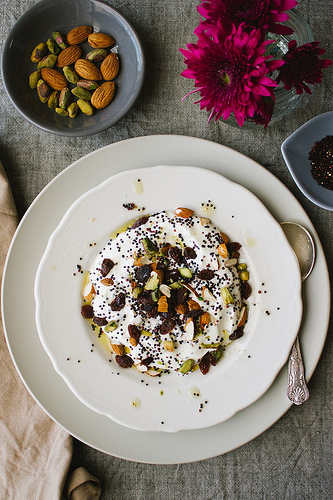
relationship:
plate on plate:
[3, 133, 332, 468] [3, 133, 332, 468]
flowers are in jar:
[185, 1, 326, 120] [208, 7, 314, 131]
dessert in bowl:
[81, 207, 252, 378] [38, 166, 302, 427]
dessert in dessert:
[81, 207, 252, 378] [81, 207, 252, 378]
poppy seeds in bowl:
[310, 134, 330, 188] [280, 111, 333, 211]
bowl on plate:
[35, 165, 304, 432] [3, 133, 332, 468]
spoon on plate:
[278, 219, 318, 405] [3, 133, 332, 468]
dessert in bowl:
[83, 209, 245, 380] [38, 166, 302, 427]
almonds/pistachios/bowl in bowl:
[2, 0, 147, 138] [0, 4, 151, 145]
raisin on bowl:
[96, 257, 110, 279] [35, 165, 304, 432]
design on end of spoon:
[287, 342, 307, 405] [276, 221, 321, 403]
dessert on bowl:
[81, 207, 252, 378] [2, 0, 156, 125]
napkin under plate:
[0, 167, 104, 497] [3, 133, 332, 468]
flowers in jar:
[179, 17, 285, 126] [207, 7, 314, 131]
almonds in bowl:
[73, 58, 104, 81] [280, 111, 333, 211]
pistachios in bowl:
[83, 45, 106, 62] [280, 111, 333, 211]